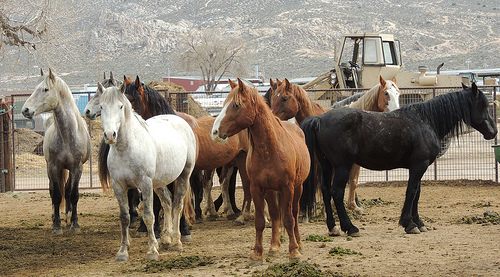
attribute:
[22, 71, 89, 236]
horse — standing, white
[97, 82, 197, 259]
horse — white, standing